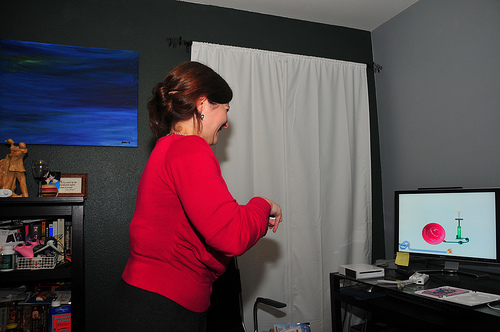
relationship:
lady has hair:
[115, 54, 284, 326] [147, 61, 234, 140]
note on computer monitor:
[395, 249, 412, 272] [394, 187, 500, 278]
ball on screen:
[417, 218, 446, 245] [385, 183, 493, 278]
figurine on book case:
[0, 139, 40, 199] [0, 196, 86, 332]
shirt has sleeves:
[121, 134, 269, 313] [175, 139, 275, 262]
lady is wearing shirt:
[117, 61, 282, 332] [125, 133, 270, 319]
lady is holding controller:
[117, 61, 282, 332] [253, 191, 292, 236]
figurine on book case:
[0, 139, 30, 198] [0, 196, 86, 332]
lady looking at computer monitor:
[117, 61, 282, 332] [394, 187, 500, 278]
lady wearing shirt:
[117, 61, 282, 332] [125, 133, 270, 319]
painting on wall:
[3, 37, 143, 151] [2, 1, 380, 330]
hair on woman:
[149, 59, 235, 131] [109, 61, 274, 330]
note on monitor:
[395, 252, 410, 267] [391, 189, 498, 265]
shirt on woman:
[125, 133, 270, 319] [109, 61, 274, 330]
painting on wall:
[0, 40, 140, 147] [2, 1, 380, 330]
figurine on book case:
[0, 139, 30, 198] [0, 195, 88, 327]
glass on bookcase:
[31, 159, 49, 197] [0, 191, 85, 326]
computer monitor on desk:
[394, 187, 500, 278] [327, 265, 491, 328]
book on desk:
[412, 282, 497, 312] [329, 260, 494, 329]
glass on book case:
[27, 159, 52, 200] [0, 196, 86, 332]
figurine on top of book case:
[0, 139, 30, 198] [0, 196, 86, 332]